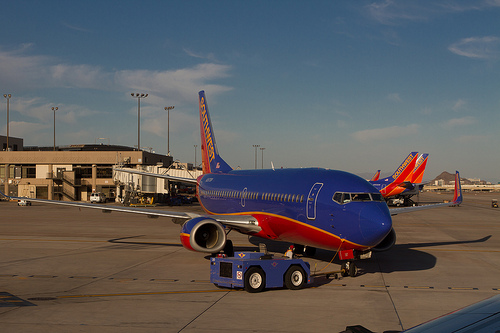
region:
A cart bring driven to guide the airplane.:
[207, 248, 312, 290]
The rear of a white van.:
[87, 190, 104, 205]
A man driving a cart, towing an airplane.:
[284, 243, 295, 261]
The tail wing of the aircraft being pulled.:
[189, 82, 225, 174]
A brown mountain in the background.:
[434, 165, 460, 185]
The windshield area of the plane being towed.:
[330, 188, 394, 208]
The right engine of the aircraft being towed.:
[177, 213, 227, 255]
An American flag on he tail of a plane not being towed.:
[382, 175, 390, 185]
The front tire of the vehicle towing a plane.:
[284, 262, 307, 287]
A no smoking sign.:
[232, 269, 249, 280]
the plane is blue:
[202, 169, 410, 267]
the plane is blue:
[187, 135, 357, 250]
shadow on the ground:
[366, 237, 441, 295]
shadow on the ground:
[375, 231, 483, 290]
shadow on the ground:
[119, 225, 264, 262]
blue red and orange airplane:
[148, 99, 395, 263]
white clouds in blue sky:
[12, 16, 69, 57]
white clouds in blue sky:
[13, 53, 63, 90]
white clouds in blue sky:
[16, 78, 93, 128]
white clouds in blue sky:
[92, 79, 180, 141]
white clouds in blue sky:
[75, 15, 173, 66]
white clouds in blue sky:
[173, 19, 251, 80]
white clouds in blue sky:
[211, 69, 291, 134]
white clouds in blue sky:
[265, 121, 373, 155]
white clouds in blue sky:
[309, 32, 470, 116]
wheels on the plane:
[343, 265, 353, 276]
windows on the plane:
[239, 189, 296, 208]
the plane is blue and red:
[168, 96, 392, 253]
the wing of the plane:
[27, 190, 182, 223]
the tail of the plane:
[190, 91, 236, 169]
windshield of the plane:
[338, 185, 379, 203]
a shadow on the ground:
[402, 235, 442, 277]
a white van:
[88, 189, 102, 201]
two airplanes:
[375, 155, 432, 210]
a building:
[9, 150, 60, 172]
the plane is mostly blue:
[70, 95, 449, 287]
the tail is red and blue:
[172, 65, 229, 190]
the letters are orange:
[193, 87, 218, 170]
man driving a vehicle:
[268, 220, 314, 282]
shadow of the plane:
[304, 206, 454, 301]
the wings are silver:
[0, 148, 254, 245]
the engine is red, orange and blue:
[167, 205, 234, 265]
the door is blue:
[297, 164, 325, 220]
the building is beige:
[3, 102, 173, 214]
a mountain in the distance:
[423, 154, 478, 191]